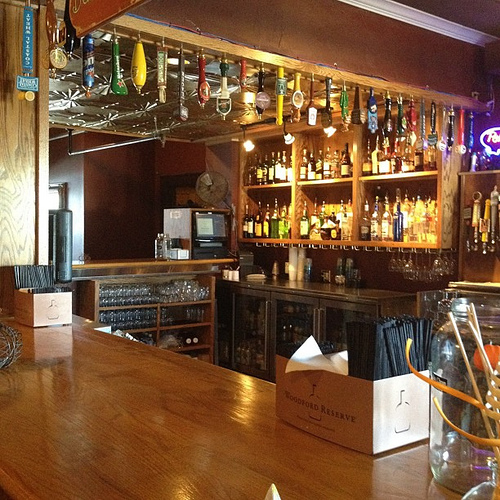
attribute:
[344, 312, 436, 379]
straws — black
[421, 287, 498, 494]
jar — glass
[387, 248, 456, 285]
wine glasses — upside down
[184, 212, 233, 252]
monitor — black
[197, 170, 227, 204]
round fan — brown